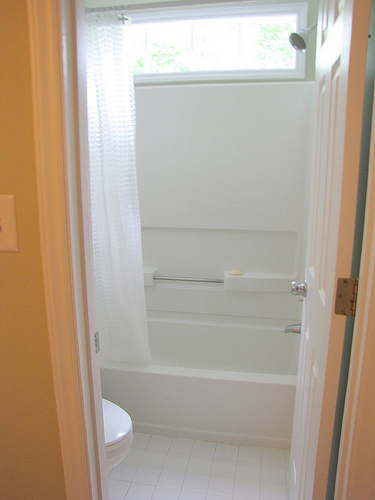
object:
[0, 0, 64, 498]
wall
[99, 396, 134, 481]
toilet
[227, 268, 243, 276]
soap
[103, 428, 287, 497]
floor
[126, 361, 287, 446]
tub wall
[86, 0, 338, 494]
bathroom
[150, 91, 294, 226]
white wall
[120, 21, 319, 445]
shower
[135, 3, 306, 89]
window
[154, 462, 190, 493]
tiles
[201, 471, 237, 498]
tiles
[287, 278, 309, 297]
knob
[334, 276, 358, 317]
hinge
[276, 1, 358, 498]
door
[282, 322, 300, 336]
faucet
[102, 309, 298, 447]
bathtub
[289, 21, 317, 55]
shower head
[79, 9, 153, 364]
white curtain